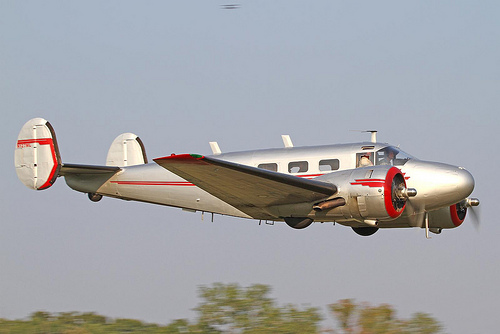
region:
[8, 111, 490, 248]
silver and red airplane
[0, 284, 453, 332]
trees on the ground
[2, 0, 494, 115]
clear blue skies in air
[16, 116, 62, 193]
the tail of the plane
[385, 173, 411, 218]
right engine propellor on plane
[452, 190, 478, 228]
left enginie propellor on plane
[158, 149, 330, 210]
right wing on the plane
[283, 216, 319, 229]
right wheel on plane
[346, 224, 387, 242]
left wheel on the plane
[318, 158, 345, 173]
small window on side of plane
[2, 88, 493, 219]
Plane flying in mid air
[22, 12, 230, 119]
The sky is blue and clear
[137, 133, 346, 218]
Wing on side of plane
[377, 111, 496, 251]
Nose on the plane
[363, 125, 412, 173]
Window on front of plane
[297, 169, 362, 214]
Exhaust on the plane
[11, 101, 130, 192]
Tail on back of plane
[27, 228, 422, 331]
Plane flying over trees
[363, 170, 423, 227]
Red on the jet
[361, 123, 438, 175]
Man flying the plane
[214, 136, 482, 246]
this is a small plane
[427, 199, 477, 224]
the plane is silver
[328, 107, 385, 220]
this is a jet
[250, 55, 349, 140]
there are no clouds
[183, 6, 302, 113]
there are no birds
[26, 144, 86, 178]
this is the tail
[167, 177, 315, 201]
this is a wing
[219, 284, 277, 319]
the trees are old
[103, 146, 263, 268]
the stripe is red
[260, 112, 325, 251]
there are three windows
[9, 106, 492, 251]
A plane is flying in the air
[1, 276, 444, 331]
The tops of green trees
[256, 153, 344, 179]
Three windows on the side of a plane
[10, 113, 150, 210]
Tail of the plane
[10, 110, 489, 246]
A plane is gray and red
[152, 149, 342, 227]
The wing of a small plane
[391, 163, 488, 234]
Two spinning propellors of a plane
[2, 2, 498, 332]
The sky appears light blue and clear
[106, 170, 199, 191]
Red stripe on side of a plane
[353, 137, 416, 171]
Front window of a plane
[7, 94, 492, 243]
silver jet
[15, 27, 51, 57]
white clouds in blue sky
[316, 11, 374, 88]
white clouds in blue sky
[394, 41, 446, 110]
white clouds in blue sky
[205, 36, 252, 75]
white clouds in blue sky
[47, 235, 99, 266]
white clouds in blue sky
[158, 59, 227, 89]
white clouds in blue sky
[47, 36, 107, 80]
white clouds in blue sky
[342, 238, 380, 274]
white clouds in blue sky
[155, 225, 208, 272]
white clouds in blue sky